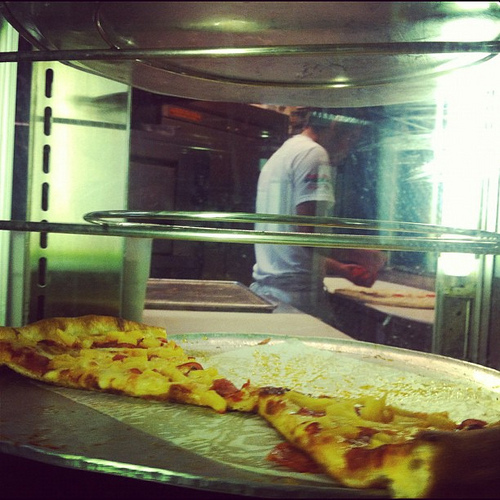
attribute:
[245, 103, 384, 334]
man — making pizza, looking down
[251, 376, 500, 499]
pizza — sliced, large, triangle shape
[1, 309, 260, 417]
pizza — sliced, large, triangle shape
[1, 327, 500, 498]
tray — metallic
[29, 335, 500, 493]
paper — greasy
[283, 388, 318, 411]
pineapple — chunked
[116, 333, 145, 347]
pineapple — chunked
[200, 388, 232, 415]
pineapple — chunked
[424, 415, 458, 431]
pineapple — chunked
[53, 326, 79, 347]
pineapple — chunked